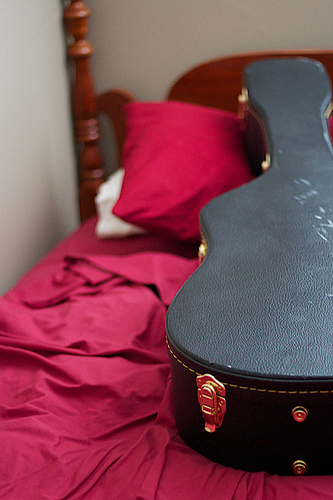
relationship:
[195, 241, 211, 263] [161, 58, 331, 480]
latch on guitar case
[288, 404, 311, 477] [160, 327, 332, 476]
stands on bottom of case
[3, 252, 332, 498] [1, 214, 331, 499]
wrinkles on sheet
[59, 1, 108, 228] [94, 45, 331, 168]
post to head board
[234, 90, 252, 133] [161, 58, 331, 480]
buckle on guitar case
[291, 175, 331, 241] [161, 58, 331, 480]
scratches on guitar case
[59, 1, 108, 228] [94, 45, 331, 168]
post on head board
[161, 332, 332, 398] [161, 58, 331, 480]
seam on guitar case